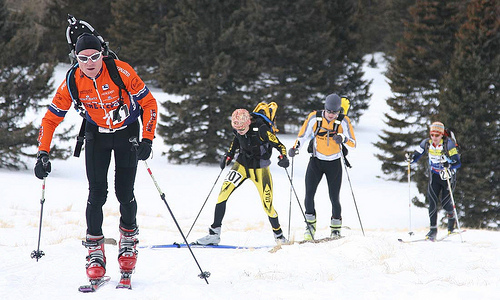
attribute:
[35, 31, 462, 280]
people — skiing, together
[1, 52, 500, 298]
snow — very bright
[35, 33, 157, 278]
man — outdoors, skiing, exercising, warm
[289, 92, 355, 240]
person — skiing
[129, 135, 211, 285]
ski pole — long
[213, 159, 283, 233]
pants — yellow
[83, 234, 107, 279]
ski boot — red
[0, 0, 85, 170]
tree — dark green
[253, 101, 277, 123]
snowshoes — yellow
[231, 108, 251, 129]
hat — multi-colored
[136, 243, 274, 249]
ski — blue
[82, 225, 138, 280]
ski boots — red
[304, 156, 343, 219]
pants — black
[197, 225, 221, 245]
ski boot — white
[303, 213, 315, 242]
ski boot — bright yellow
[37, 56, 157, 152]
jacket — orange